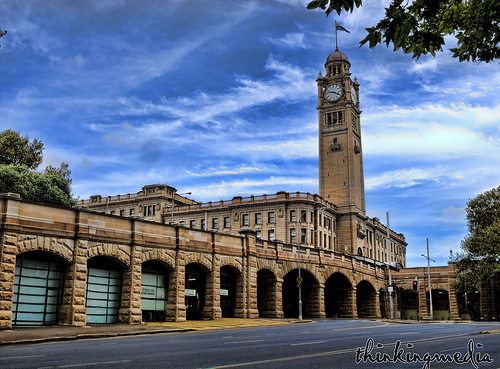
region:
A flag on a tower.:
[332, 18, 351, 50]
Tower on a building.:
[314, 46, 367, 214]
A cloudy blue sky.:
[1, 1, 499, 268]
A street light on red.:
[410, 277, 419, 292]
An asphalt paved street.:
[0, 315, 498, 367]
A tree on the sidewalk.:
[445, 183, 498, 295]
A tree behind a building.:
[0, 28, 83, 209]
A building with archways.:
[2, 190, 499, 330]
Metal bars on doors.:
[10, 250, 168, 329]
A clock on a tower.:
[323, 81, 343, 104]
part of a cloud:
[249, 109, 274, 140]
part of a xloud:
[288, 130, 305, 147]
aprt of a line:
[340, 347, 355, 367]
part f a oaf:
[336, 305, 358, 332]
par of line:
[341, 333, 364, 353]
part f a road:
[323, 316, 345, 346]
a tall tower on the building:
[317, 48, 366, 211]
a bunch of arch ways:
[11, 247, 481, 324]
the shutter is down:
[12, 250, 52, 325]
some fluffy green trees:
[1, 130, 76, 203]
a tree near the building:
[452, 186, 497, 286]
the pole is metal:
[421, 239, 438, 314]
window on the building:
[267, 212, 274, 223]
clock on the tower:
[325, 81, 341, 101]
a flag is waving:
[333, 19, 346, 47]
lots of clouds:
[0, 2, 499, 265]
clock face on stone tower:
[319, 81, 343, 102]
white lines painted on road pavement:
[209, 327, 325, 348]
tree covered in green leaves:
[446, 188, 498, 287]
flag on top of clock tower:
[326, 19, 358, 53]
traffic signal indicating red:
[408, 275, 423, 294]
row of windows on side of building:
[236, 207, 280, 224]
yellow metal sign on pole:
[294, 271, 303, 286]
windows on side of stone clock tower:
[318, 108, 351, 130]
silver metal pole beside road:
[419, 231, 440, 325]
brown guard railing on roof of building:
[194, 191, 311, 201]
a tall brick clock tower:
[310, 15, 367, 216]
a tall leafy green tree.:
[0, 125, 85, 211]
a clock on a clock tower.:
[316, 75, 345, 110]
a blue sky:
[108, 65, 178, 100]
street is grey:
[210, 335, 280, 352]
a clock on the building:
[322, 83, 345, 103]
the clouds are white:
[135, 112, 187, 142]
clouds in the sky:
[123, 92, 201, 137]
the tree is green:
[3, 127, 55, 193]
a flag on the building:
[330, 20, 357, 40]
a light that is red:
[410, 275, 420, 288]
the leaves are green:
[382, 23, 437, 49]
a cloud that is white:
[400, 126, 462, 158]